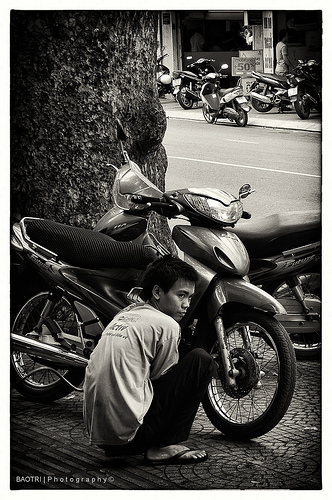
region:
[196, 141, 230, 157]
this is the road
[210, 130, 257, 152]
the road is clean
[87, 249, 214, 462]
this is a man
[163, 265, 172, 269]
this is the hair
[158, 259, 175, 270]
the hair is black in color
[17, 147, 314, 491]
these are some motorcycles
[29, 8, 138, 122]
this is a hedge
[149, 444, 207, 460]
this is a slipper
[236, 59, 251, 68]
these are two digits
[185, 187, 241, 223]
this is a headlight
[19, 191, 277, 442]
a young man stooping by a bike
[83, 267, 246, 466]
he looks very suspiscious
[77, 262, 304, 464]
he is looking worried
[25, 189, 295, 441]
this is a modern motorcycle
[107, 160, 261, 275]
the front end of the motorcycle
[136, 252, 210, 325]
this young man is Asian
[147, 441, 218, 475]
he has on sandals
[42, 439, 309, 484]
the ground is made out paved stones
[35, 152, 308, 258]
two motorcycles in the scene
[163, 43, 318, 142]
a lot of motorcycles in the background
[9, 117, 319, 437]
Motorcycles parked on the sidewalk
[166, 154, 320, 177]
White line on the road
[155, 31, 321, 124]
Motorcycles parked on the other side of the road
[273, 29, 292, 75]
Person standing next to a motorcycle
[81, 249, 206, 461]
Boy squats by a motorcycle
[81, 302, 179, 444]
Shirt on the boy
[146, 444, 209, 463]
Flip flops on the boy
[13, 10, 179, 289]
Big tree on the sidewalk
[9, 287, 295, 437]
Wheels of the motorcycle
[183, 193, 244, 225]
Light of the motorcycle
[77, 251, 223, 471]
the man croutches by the bike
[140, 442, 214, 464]
the flip flop on the mans foot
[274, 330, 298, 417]
the tread on the bike tire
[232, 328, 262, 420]
the spokes on the bike tire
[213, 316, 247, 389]
the shocks of the bike tire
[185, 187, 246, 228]
the front light on the bike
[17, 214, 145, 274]
the seat of the bike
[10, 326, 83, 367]
the exhuast for the motrocycle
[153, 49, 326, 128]
the lines of parked bikes on the sidewalk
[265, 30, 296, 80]
the man in front of the building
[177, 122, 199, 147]
black asphalt surface of the road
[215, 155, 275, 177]
white line painted on the road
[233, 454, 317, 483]
grey stone bricks of the sidewalk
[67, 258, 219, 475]
a man squatting next to a motorcycle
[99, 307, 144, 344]
black lettering on a grey shirt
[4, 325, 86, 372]
grey metal exhaust pipe of the motorcycle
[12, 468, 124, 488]
logo and copyright of the photographer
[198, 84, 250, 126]
a scooter parked in the street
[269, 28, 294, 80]
a woman standing outside of a shop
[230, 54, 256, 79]
a grey and black sign out front of a shop